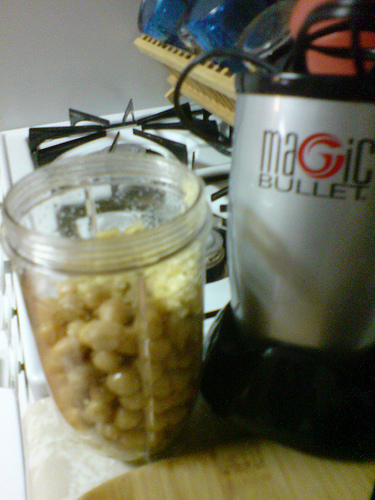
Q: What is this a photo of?
A: A blender.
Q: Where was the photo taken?
A: In a kitchen.